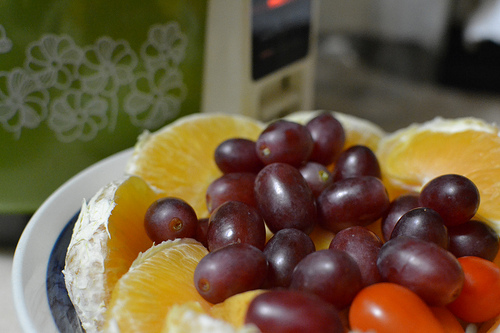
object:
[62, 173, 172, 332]
orange slice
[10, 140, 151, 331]
plate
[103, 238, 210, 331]
orange slice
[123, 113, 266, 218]
orange slice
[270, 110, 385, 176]
orange slice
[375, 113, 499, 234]
orange slice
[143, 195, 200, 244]
grapes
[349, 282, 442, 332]
tomato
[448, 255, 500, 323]
tomato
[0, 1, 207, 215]
object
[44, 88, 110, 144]
flowers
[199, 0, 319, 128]
appliance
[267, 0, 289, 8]
light